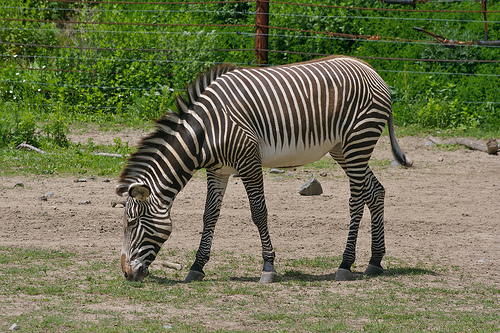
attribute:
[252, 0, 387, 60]
leaves — green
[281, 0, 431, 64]
leaves — green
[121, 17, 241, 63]
leaves — green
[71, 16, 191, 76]
leaves — green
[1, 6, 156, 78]
leaves — green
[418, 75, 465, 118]
leaves — green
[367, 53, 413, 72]
leaves — green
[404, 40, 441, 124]
leaves — green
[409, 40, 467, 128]
leaves — green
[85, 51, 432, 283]
zebra — black, white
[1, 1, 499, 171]
bush — green